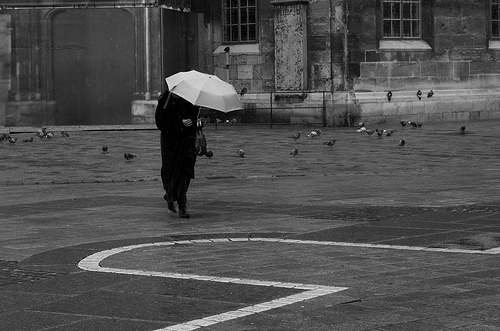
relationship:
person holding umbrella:
[155, 91, 207, 220] [173, 73, 242, 121]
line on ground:
[74, 234, 496, 329] [4, 130, 481, 330]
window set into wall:
[372, 2, 434, 52] [365, 8, 446, 59]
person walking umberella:
[155, 91, 207, 220] [165, 69, 245, 115]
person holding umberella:
[155, 91, 207, 220] [165, 69, 245, 115]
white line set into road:
[92, 227, 497, 318] [18, 126, 496, 323]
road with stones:
[18, 126, 496, 323] [253, 205, 410, 283]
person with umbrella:
[155, 91, 207, 220] [135, 58, 301, 114]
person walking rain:
[156, 91, 206, 216] [12, 222, 479, 312]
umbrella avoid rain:
[164, 67, 245, 112] [7, 9, 470, 95]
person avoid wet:
[155, 91, 207, 220] [144, 74, 228, 135]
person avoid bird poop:
[155, 91, 207, 220] [249, 298, 306, 326]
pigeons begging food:
[359, 125, 376, 137] [98, 126, 436, 180]